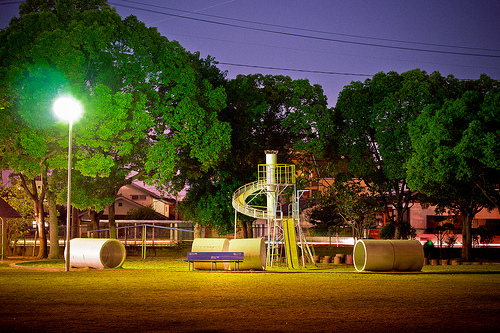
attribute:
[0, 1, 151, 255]
tall tree — green, leafy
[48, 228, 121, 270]
tube — large, cylindrical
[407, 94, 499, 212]
leaves — green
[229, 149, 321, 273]
slide — large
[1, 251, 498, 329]
ground — brown, green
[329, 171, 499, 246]
building — large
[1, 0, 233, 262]
leafy tree — tall, green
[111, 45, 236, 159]
trees — large, green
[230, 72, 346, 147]
trees — large, green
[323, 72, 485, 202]
trees — large, green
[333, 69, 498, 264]
tree — tall, leafy, green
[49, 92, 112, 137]
light — on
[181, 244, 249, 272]
bench — purple, blue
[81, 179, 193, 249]
house — 2-story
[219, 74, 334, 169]
tree — green, tall, leafy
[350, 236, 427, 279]
tube — large, white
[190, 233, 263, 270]
tube — large, white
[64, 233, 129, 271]
tube — large, white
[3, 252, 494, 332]
grass — green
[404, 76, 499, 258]
tree — green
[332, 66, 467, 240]
tree — green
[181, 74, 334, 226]
tree — green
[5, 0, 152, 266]
tree — green